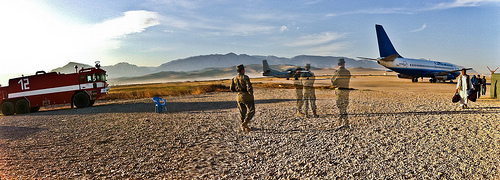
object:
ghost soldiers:
[329, 58, 351, 130]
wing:
[432, 68, 473, 76]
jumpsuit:
[229, 64, 256, 132]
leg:
[243, 103, 255, 122]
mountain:
[49, 49, 477, 85]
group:
[451, 68, 486, 109]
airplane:
[262, 59, 313, 80]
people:
[476, 75, 483, 99]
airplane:
[356, 24, 473, 84]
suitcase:
[452, 93, 461, 102]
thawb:
[456, 74, 475, 96]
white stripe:
[8, 82, 104, 99]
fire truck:
[0, 60, 110, 115]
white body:
[377, 57, 460, 72]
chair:
[152, 96, 169, 113]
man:
[451, 69, 477, 109]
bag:
[467, 88, 477, 102]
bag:
[452, 92, 461, 103]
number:
[18, 78, 30, 90]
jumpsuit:
[301, 63, 319, 117]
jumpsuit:
[293, 68, 303, 116]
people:
[470, 75, 480, 99]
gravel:
[0, 90, 500, 180]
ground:
[3, 72, 500, 180]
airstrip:
[0, 69, 500, 180]